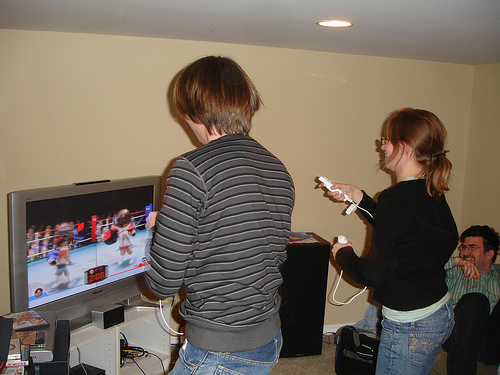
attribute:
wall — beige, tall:
[1, 27, 497, 337]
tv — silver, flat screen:
[3, 170, 168, 335]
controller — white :
[316, 175, 349, 203]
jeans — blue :
[371, 292, 461, 372]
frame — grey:
[8, 195, 28, 312]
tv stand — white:
[27, 305, 168, 374]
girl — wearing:
[324, 108, 459, 373]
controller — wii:
[302, 173, 355, 207]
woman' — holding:
[329, 72, 461, 328]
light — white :
[311, 16, 355, 31]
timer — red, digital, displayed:
[84, 266, 108, 283]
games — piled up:
[3, 309, 48, 351]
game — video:
[320, 0, 362, 40]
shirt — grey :
[144, 139, 316, 339]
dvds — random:
[2, 305, 54, 374]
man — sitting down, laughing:
[442, 221, 499, 373]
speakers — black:
[281, 237, 325, 360]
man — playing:
[156, 50, 360, 315]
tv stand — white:
[55, 290, 187, 375]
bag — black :
[332, 325, 379, 374]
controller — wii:
[311, 167, 359, 214]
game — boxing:
[10, 171, 166, 311]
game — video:
[28, 187, 164, 302]